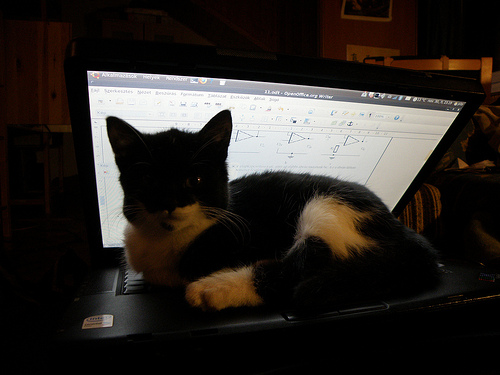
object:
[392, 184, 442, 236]
bedspread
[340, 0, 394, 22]
wall hanging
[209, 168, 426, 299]
hair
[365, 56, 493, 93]
furniture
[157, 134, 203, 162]
hair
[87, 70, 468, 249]
program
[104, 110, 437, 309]
fur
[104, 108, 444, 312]
animal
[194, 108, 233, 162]
ear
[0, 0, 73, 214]
wood panels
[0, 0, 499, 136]
wall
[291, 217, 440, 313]
cat tail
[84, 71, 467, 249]
intel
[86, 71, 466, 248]
screen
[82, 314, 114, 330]
sticker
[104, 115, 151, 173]
ear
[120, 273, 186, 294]
keyboard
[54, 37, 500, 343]
computer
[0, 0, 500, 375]
room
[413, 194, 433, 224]
portion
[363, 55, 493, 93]
wood